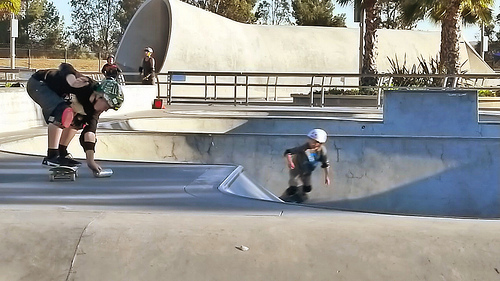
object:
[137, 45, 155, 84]
people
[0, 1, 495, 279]
outdoors